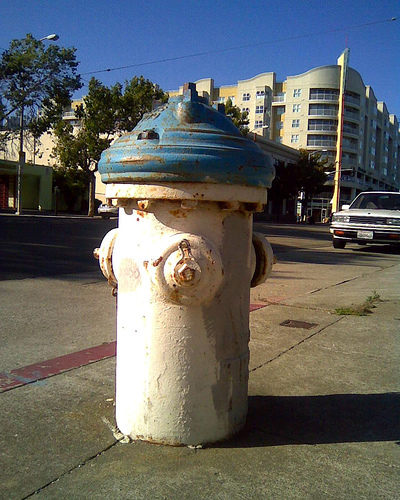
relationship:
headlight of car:
[388, 217, 399, 223] [329, 191, 398, 248]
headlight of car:
[333, 215, 349, 221] [329, 191, 398, 248]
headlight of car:
[314, 222, 382, 252] [325, 189, 398, 252]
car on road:
[329, 180, 399, 265] [275, 230, 348, 285]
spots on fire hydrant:
[151, 254, 164, 267] [95, 82, 281, 449]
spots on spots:
[142, 258, 148, 271] [151, 254, 164, 267]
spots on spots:
[210, 258, 216, 266] [142, 258, 148, 271]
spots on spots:
[208, 246, 213, 254] [210, 258, 216, 266]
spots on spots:
[134, 216, 142, 224] [208, 246, 213, 254]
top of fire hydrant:
[92, 86, 279, 191] [95, 82, 281, 449]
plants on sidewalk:
[313, 241, 390, 365] [2, 244, 399, 497]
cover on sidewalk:
[280, 317, 317, 326] [282, 331, 312, 361]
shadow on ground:
[205, 390, 397, 448] [3, 207, 397, 497]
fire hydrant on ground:
[102, 98, 283, 448] [9, 255, 397, 488]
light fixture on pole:
[36, 30, 59, 44] [12, 52, 25, 214]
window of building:
[288, 87, 300, 95] [195, 48, 399, 218]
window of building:
[289, 102, 302, 113] [1, 47, 398, 227]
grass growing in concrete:
[327, 290, 380, 316] [3, 256, 399, 491]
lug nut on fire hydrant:
[178, 264, 195, 284] [93, 81, 277, 445]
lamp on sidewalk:
[7, 26, 62, 216] [0, 210, 398, 234]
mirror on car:
[335, 199, 348, 211] [325, 189, 398, 252]